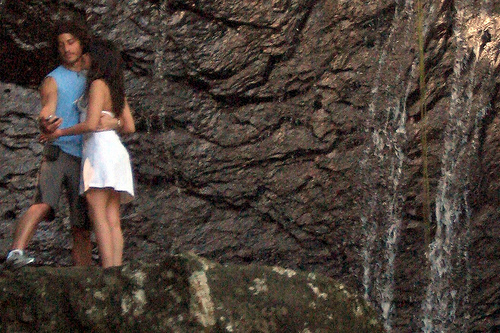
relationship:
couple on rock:
[5, 24, 137, 266] [1, 254, 381, 330]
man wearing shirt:
[5, 25, 91, 267] [48, 64, 85, 157]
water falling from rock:
[354, 4, 499, 330] [344, 1, 500, 330]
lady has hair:
[37, 39, 135, 266] [81, 36, 128, 116]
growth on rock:
[412, 5, 433, 255] [344, 1, 500, 330]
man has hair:
[5, 25, 91, 267] [55, 25, 88, 51]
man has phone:
[5, 25, 91, 267] [44, 114, 60, 123]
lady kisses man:
[37, 39, 135, 266] [5, 25, 91, 267]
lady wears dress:
[37, 39, 135, 266] [76, 96, 136, 208]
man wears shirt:
[5, 25, 91, 267] [48, 64, 85, 157]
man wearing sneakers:
[5, 25, 91, 267] [5, 250, 38, 265]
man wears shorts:
[5, 25, 91, 267] [35, 146, 88, 227]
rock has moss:
[1, 254, 381, 330] [1, 253, 383, 329]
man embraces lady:
[5, 25, 91, 267] [37, 39, 135, 266]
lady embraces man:
[37, 39, 135, 266] [5, 25, 91, 267]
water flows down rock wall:
[354, 4, 499, 330] [1, 1, 496, 332]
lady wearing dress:
[37, 39, 135, 266] [76, 96, 136, 208]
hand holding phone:
[40, 115, 62, 134] [44, 114, 60, 123]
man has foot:
[5, 25, 91, 267] [5, 251, 35, 265]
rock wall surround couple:
[1, 1, 496, 332] [5, 24, 137, 266]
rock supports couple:
[1, 254, 381, 330] [5, 24, 137, 266]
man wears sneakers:
[5, 25, 91, 267] [5, 250, 38, 265]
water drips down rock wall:
[354, 4, 499, 330] [1, 1, 496, 332]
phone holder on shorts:
[44, 145, 60, 161] [35, 146, 88, 227]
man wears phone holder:
[5, 25, 91, 267] [44, 145, 60, 161]